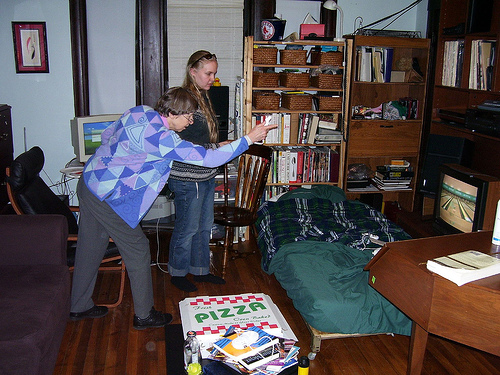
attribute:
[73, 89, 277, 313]
woman — holding, old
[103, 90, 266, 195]
women — playiing, playing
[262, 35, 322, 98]
baskets — wicker, storage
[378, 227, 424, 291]
table — wooden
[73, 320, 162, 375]
floor — wood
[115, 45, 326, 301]
people — playing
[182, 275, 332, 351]
box — cardboard, pizza, white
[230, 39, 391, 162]
bookcase — here, wooden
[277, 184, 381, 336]
cot — rollaway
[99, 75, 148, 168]
lady — older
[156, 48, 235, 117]
lady — younger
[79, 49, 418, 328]
bedroom — here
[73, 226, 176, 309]
pants — grey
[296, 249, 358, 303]
cover — green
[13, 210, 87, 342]
couch — purple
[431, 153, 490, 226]
television — on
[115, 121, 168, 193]
sweater — purple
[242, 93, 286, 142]
controller — white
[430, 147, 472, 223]
screen — displaying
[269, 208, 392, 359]
bed — pullout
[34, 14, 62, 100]
frame — brown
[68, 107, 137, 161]
monitor — framed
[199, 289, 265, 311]
pizza — word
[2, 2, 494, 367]
room — messy